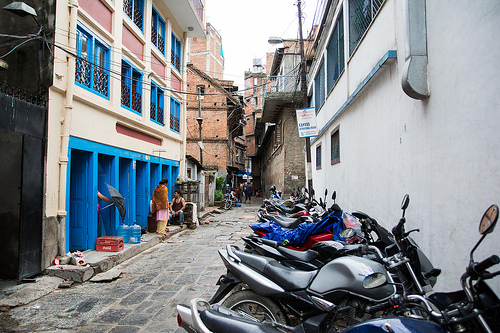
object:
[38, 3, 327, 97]
wires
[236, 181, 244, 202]
people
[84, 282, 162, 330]
street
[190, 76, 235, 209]
post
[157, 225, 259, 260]
street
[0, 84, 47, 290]
gate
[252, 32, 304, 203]
house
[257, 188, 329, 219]
motorcycle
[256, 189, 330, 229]
motorcycle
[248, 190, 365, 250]
motorcycle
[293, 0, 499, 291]
building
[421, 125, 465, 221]
sidewalk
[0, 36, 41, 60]
wires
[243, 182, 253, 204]
people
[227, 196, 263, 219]
street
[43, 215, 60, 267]
sidewalk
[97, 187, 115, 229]
lady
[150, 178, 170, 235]
lady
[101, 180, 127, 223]
umbrella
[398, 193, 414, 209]
mirror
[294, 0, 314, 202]
wood pole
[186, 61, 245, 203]
building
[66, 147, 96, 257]
door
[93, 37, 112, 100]
blue window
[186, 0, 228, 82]
building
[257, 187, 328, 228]
motor cycles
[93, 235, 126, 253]
crates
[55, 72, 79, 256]
pipe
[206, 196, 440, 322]
motorcycle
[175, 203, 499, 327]
motorcycle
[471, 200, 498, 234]
mirror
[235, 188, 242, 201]
person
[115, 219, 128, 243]
water bottles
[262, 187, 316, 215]
motorcycles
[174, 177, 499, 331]
row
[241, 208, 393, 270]
bike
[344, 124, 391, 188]
wall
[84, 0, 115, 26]
wall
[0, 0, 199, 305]
building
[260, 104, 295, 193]
stone built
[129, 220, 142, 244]
bottles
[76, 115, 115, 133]
sidewalk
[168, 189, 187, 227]
man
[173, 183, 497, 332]
line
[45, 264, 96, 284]
brick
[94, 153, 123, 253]
doors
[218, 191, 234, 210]
cycle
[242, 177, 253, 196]
opening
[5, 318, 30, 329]
ground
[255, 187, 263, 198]
people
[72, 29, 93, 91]
window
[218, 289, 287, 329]
tire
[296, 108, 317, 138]
paint